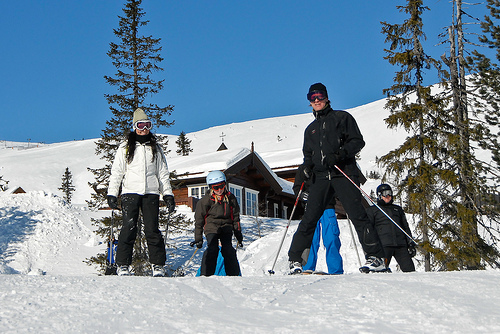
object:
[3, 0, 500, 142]
sky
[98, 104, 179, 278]
woman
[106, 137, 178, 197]
jacket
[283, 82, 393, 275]
man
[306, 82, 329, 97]
hat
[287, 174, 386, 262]
pants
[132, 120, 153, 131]
goggles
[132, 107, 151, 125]
helmet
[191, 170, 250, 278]
kid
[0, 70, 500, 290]
hill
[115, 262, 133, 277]
boots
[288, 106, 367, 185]
coat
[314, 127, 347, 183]
black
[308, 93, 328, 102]
sunglasses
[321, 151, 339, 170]
gloves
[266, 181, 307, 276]
poles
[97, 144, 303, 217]
building